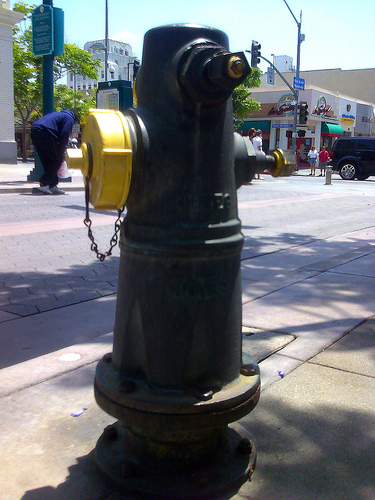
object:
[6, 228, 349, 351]
shadows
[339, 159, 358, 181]
rear wheel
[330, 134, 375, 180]
vehicle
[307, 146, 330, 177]
people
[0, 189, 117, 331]
street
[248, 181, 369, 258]
street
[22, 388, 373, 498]
shade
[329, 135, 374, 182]
automobile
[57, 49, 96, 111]
tree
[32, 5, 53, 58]
street sign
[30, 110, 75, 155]
shirt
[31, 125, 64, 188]
pants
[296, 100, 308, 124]
traffic signal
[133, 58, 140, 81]
traffic signal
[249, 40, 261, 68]
traffic light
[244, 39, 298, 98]
arm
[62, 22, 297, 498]
hydrant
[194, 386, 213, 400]
black bolt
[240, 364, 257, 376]
black bolt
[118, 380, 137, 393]
black bolt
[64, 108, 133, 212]
stem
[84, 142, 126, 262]
chain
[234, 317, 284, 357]
panel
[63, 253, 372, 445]
sidewalk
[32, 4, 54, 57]
sign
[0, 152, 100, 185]
sidewalk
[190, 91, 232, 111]
floor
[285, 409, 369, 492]
shade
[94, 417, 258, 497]
bolt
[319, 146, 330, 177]
person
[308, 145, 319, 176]
person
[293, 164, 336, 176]
sidewalk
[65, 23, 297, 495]
fire hydrant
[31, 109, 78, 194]
man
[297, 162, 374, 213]
street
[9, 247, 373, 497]
sidewalk